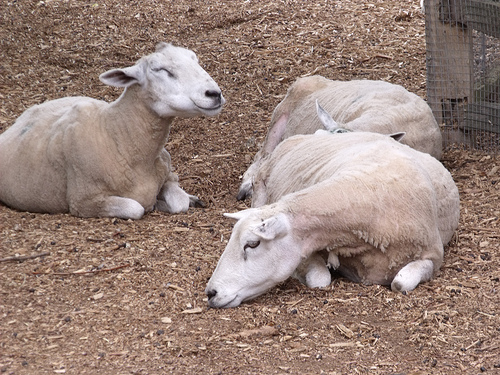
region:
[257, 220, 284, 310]
This lamb has a large ear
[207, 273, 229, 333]
There is a black nose that is great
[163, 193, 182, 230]
There is a white leg that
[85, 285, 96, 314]
There are wooden pieces that are visible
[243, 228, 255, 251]
There is a black eye that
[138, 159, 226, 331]
Jackson Mingus took this photo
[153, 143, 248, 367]
This photo was taken in the season of summer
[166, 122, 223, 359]
Zander Zeke owns this photo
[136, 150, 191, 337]
This photo was taken with a telephoto lens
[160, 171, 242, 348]
This photo is very artistic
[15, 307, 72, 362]
Small wooden ships on the ground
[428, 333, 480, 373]
Small wooden ships on the ground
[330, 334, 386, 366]
Small wooden ships on the ground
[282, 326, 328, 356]
Small wooden ships on the ground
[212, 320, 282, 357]
Small wooden ships on the ground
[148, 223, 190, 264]
Small wooden ships on the ground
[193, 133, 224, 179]
Small wooden ships on the ground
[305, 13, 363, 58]
Small wooden ships on the ground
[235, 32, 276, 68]
Small wooden ships on the ground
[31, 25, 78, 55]
Small wooden ships on the ground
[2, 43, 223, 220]
THIS IS A ANIMAL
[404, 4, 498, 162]
THIS IS A CAGE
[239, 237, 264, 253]
THIS IS HIS EYE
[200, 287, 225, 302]
THIS IS HIS NOSE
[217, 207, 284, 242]
THESE ARE HIS EARS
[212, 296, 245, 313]
THIS IS HIS MOUTH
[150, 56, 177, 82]
HIS EYE IS CLOSED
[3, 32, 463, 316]
THREE ANIMALS LAYING DOWN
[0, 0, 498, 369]
THIS IS THE GROUND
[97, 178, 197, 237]
THESE ARE HIS ARMS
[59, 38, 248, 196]
small white goat with eyes closed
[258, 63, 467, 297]
two goats lying together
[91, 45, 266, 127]
goat with a smile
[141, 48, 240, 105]
little goat with eyes closed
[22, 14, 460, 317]
three goats near each other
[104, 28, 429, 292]
three goats lying down on ground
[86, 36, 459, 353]
three goats lying in the dirt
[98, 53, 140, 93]
small goat ear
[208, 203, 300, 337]
goat with nose on the ground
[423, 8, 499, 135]
metal crate behind goat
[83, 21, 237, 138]
the sheep is happy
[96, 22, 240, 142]
the sheep is happy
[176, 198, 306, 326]
sheep is sniffing the ground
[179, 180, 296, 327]
sheep is sniffing the ground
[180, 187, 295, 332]
sheep is sniffing the ground